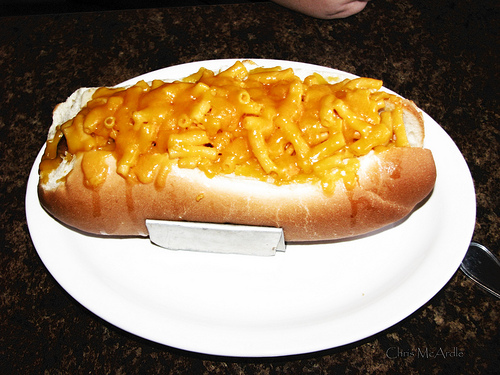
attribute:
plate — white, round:
[24, 57, 479, 362]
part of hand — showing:
[272, 2, 369, 18]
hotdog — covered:
[58, 137, 71, 156]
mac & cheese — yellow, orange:
[67, 63, 406, 178]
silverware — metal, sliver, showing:
[460, 244, 499, 302]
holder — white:
[145, 220, 286, 258]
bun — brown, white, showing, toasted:
[40, 85, 437, 243]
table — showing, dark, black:
[4, 7, 499, 374]